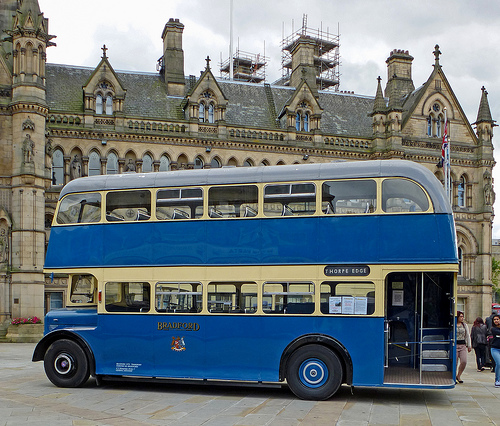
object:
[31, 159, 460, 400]
bus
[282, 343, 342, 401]
wheel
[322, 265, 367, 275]
sign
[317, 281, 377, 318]
window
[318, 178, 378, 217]
window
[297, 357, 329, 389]
hubcap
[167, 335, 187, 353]
logo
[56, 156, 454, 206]
roof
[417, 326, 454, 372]
steps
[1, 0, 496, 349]
building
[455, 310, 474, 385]
person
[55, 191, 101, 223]
window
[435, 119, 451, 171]
flag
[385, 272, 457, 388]
door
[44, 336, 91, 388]
front wheel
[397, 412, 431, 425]
slab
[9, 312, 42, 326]
flower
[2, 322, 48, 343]
planter box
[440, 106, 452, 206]
pole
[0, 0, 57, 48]
spire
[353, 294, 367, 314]
paper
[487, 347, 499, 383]
jeans